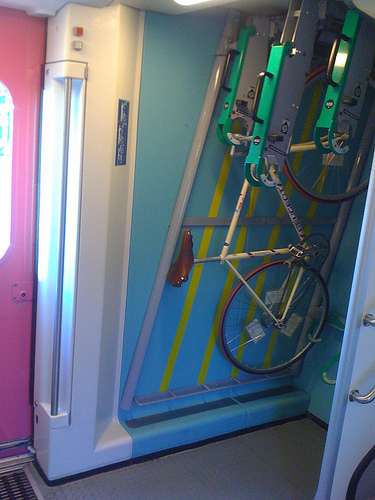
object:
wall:
[118, 10, 373, 418]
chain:
[272, 233, 329, 331]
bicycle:
[167, 63, 375, 373]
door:
[0, 6, 46, 455]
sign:
[114, 97, 130, 166]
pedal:
[288, 241, 305, 264]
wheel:
[216, 257, 330, 376]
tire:
[282, 63, 375, 205]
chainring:
[305, 241, 326, 271]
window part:
[1, 175, 8, 193]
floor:
[0, 419, 327, 498]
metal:
[262, 88, 267, 119]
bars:
[230, 145, 246, 156]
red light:
[75, 27, 84, 40]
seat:
[167, 226, 196, 287]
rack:
[118, 8, 241, 410]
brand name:
[271, 178, 306, 240]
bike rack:
[216, 25, 255, 149]